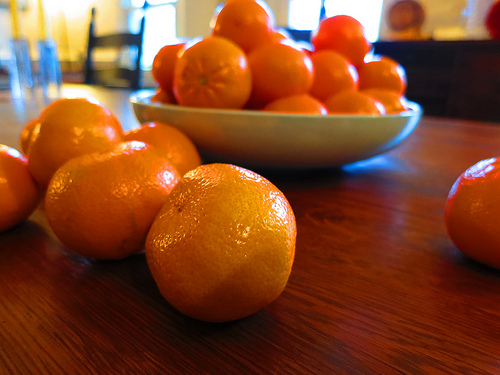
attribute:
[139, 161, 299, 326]
orange — middle, part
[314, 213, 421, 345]
table — brown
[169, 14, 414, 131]
oranges — group